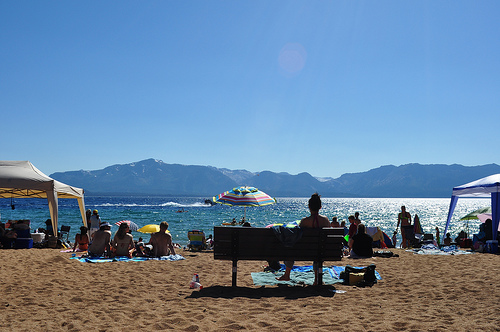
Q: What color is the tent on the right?
A: Blue.